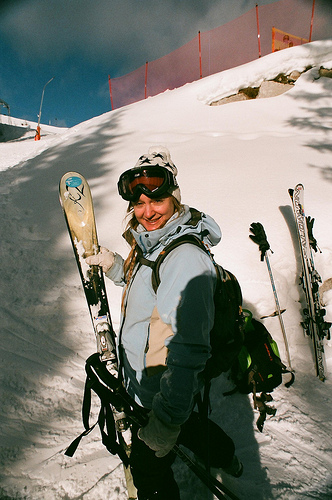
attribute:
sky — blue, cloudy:
[1, 1, 332, 128]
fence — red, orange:
[107, 1, 331, 111]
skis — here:
[60, 170, 145, 499]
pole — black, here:
[287, 183, 327, 384]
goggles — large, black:
[118, 166, 175, 202]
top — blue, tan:
[106, 205, 222, 432]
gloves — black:
[249, 223, 275, 261]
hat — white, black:
[134, 146, 181, 199]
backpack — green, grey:
[153, 234, 243, 386]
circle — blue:
[67, 176, 83, 190]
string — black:
[135, 255, 158, 269]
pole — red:
[107, 77, 117, 112]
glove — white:
[138, 412, 182, 459]